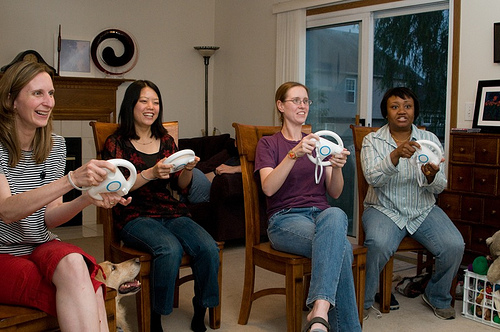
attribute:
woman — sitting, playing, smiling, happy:
[2, 59, 111, 331]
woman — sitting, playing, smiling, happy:
[103, 77, 219, 330]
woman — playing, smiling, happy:
[256, 81, 363, 331]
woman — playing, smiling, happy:
[361, 87, 466, 320]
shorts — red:
[0, 238, 107, 317]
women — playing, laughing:
[2, 59, 466, 332]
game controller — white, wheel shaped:
[66, 155, 137, 201]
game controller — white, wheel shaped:
[164, 149, 196, 173]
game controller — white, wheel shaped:
[306, 128, 343, 182]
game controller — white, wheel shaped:
[408, 137, 442, 169]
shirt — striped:
[3, 132, 66, 255]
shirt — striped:
[361, 122, 447, 236]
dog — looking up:
[96, 255, 143, 331]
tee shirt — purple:
[253, 131, 329, 210]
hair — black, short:
[116, 77, 167, 140]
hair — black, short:
[379, 87, 421, 125]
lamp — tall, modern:
[193, 44, 219, 134]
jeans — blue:
[120, 218, 220, 314]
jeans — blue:
[266, 206, 364, 331]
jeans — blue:
[361, 206, 466, 309]